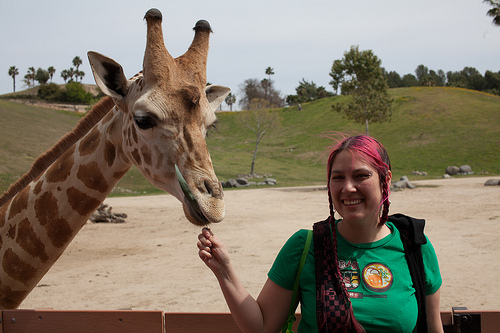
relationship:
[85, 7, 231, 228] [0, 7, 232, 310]
head of giraffe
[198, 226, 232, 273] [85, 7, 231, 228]
first near head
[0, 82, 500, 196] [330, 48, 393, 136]
hill with tree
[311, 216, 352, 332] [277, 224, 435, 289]
bag over shoulder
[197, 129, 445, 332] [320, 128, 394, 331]
woman with hair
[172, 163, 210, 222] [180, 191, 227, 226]
leaf in mouth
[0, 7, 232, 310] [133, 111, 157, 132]
giraffe has eye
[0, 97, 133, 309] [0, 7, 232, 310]
neck of giraffe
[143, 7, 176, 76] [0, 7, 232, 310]
horn of giraffe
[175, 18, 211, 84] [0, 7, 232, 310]
horn of giraffe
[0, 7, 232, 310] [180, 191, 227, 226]
giraffe has mouth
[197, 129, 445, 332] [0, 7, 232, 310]
woman feeding giraffe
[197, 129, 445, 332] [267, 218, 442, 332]
woman has shirt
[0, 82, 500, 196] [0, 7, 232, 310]
hill behind giraffe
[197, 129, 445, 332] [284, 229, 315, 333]
woman has strap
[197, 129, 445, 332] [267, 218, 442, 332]
woman wearing shirt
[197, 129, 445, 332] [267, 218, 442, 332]
woman in shirt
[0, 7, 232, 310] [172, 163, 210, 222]
giraffe grazing on leaf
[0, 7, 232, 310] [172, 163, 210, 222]
giraffe eating leaf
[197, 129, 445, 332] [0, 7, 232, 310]
woman next to giraffe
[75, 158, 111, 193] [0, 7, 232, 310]
spot on giraffe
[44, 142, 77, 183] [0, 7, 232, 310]
spot on giraffe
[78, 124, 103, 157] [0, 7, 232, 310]
spot on giraffe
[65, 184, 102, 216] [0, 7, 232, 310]
spot on giraffe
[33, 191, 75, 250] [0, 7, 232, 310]
spot on giraffe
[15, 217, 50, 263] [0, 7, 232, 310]
spot on giraffe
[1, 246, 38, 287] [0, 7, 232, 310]
spot on giraffe